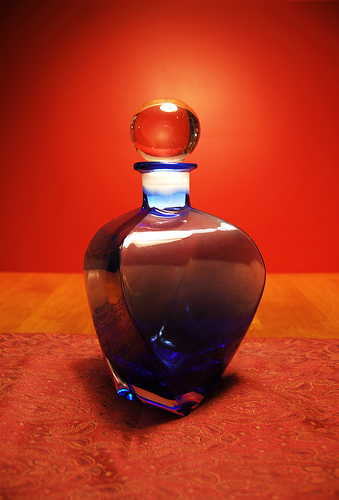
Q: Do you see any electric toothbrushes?
A: No, there are no electric toothbrushes.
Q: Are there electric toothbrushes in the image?
A: No, there are no electric toothbrushes.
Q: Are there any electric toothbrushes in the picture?
A: No, there are no electric toothbrushes.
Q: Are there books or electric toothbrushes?
A: No, there are no electric toothbrushes or books.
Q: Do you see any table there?
A: Yes, there is a table.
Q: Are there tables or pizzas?
A: Yes, there is a table.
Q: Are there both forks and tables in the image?
A: No, there is a table but no forks.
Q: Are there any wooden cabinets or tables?
A: Yes, there is a wood table.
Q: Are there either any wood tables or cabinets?
A: Yes, there is a wood table.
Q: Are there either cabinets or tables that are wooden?
A: Yes, the table is wooden.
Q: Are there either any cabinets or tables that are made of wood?
A: Yes, the table is made of wood.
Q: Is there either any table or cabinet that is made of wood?
A: Yes, the table is made of wood.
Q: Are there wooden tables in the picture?
A: Yes, there is a wood table.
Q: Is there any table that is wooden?
A: Yes, there is a table that is wooden.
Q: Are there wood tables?
A: Yes, there is a table that is made of wood.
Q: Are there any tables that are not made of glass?
A: Yes, there is a table that is made of wood.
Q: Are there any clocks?
A: No, there are no clocks.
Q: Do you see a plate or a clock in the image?
A: No, there are no clocks or plates.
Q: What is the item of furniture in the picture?
A: The piece of furniture is a table.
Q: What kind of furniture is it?
A: The piece of furniture is a table.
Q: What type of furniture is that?
A: This is a table.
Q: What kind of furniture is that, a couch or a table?
A: This is a table.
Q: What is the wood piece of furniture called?
A: The piece of furniture is a table.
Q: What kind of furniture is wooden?
A: The furniture is a table.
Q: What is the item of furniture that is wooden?
A: The piece of furniture is a table.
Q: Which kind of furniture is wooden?
A: The furniture is a table.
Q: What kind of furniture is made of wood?
A: The furniture is a table.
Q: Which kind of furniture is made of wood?
A: The furniture is a table.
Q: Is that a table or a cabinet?
A: That is a table.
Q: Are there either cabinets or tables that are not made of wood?
A: No, there is a table but it is made of wood.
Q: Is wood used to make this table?
A: Yes, the table is made of wood.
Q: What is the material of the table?
A: The table is made of wood.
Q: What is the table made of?
A: The table is made of wood.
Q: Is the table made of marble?
A: No, the table is made of wood.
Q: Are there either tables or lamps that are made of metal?
A: No, there is a table but it is made of wood.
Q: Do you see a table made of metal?
A: No, there is a table but it is made of wood.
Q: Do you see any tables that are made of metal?
A: No, there is a table but it is made of wood.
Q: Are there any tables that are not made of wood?
A: No, there is a table but it is made of wood.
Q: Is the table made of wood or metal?
A: The table is made of wood.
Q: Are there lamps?
A: No, there are no lamps.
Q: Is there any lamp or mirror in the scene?
A: No, there are no lamps or mirrors.